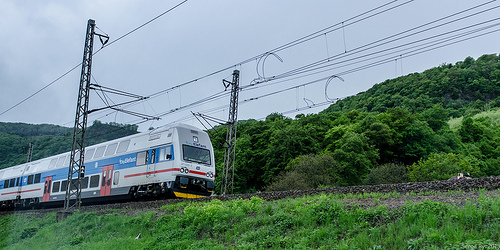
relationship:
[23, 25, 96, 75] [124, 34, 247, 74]
clouds in sky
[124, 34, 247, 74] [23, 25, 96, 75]
sky with clouds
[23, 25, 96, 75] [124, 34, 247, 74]
clouds with sky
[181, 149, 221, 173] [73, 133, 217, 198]
windshield on train